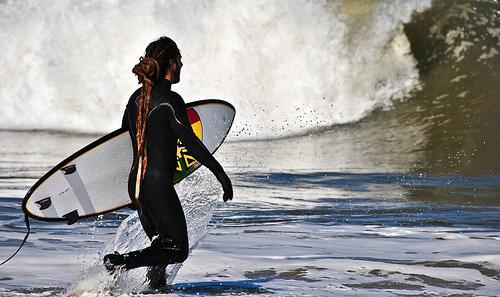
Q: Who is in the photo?
A: A man.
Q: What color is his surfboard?
A: White.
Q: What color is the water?
A: Blue.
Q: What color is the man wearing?
A: Black.